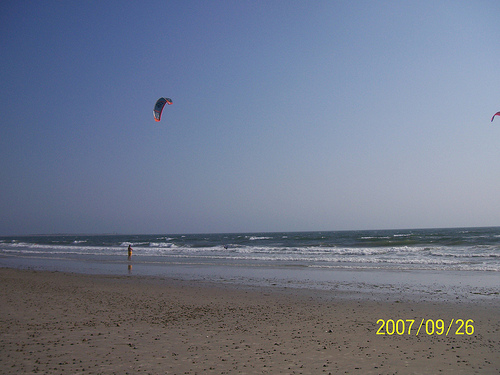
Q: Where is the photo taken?
A: Beach.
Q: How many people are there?
A: One.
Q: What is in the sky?
A: Kites.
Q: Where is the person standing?
A: Shore.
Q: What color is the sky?
A: Blue.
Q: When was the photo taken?
A: Morning.